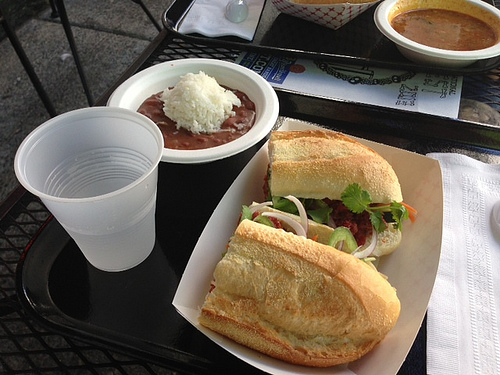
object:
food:
[137, 71, 419, 366]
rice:
[158, 71, 241, 135]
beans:
[135, 82, 258, 151]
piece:
[321, 196, 373, 246]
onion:
[261, 212, 307, 239]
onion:
[284, 194, 309, 233]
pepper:
[328, 226, 358, 254]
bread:
[196, 218, 402, 369]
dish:
[373, 0, 500, 68]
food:
[389, 9, 498, 52]